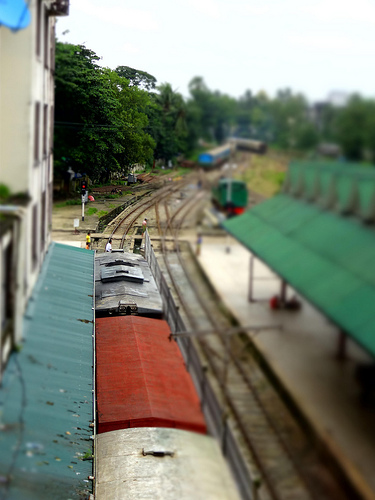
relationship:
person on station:
[83, 228, 95, 249] [0, 160, 375, 500]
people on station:
[106, 240, 112, 253] [0, 160, 375, 500]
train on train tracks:
[84, 243, 251, 497] [103, 177, 368, 497]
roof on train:
[92, 245, 171, 313] [92, 248, 245, 499]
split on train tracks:
[47, 229, 195, 242] [103, 177, 368, 497]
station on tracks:
[0, 160, 375, 500] [95, 177, 373, 496]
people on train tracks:
[75, 186, 94, 223] [103, 177, 368, 497]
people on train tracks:
[64, 185, 102, 234] [103, 177, 368, 497]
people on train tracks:
[73, 189, 120, 251] [103, 177, 368, 497]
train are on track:
[92, 248, 245, 499] [94, 155, 369, 497]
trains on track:
[195, 136, 246, 174] [94, 155, 369, 497]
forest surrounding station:
[57, 44, 365, 185] [3, 160, 370, 494]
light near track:
[79, 186, 87, 216] [113, 166, 329, 498]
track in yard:
[113, 166, 329, 498] [59, 144, 374, 493]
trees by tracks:
[59, 43, 193, 195] [106, 153, 318, 494]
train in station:
[92, 248, 245, 499] [55, 150, 372, 495]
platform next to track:
[174, 211, 373, 493] [98, 171, 365, 499]